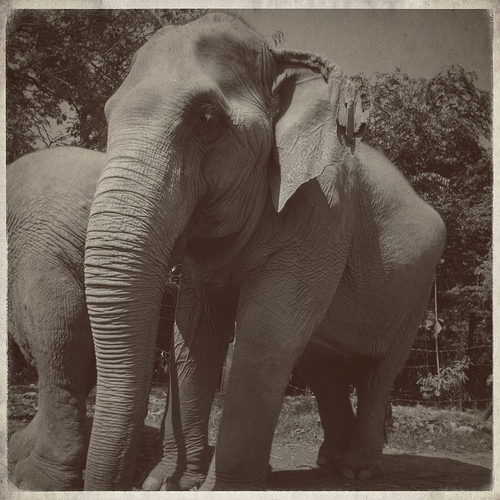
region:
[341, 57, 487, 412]
a tall tree behind the elephant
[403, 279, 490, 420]
a wire fence between the elephant and the trees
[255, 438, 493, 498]
the ground beneath the elephant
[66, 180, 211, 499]
the long elephant trunk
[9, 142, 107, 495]
the second elephant to the left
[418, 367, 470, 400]
some leaves sticking through the fence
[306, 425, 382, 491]
the rear feet of the elephant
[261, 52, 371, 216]
the large ear of the elephant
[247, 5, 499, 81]
the sky above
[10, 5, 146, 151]
the tree in the corner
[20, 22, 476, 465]
two elephants posing for a picture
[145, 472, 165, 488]
a large toe on an elephant foot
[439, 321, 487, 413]
a metal barbed wire fence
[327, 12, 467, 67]
the sky above the elephants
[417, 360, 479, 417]
a plant growing near a fence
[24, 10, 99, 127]
tall trees next the elephant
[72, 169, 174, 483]
a long elephant trunk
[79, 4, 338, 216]
an elephant head with an eye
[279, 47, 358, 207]
a large ear flaps on an elephant head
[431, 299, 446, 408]
a wooden pole supports a fence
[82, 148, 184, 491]
an elephant's trunk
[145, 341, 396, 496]
the elephant's legs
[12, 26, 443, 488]
elephants in a park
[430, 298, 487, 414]
vegetation in the park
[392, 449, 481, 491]
part of the earth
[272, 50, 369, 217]
the elephant's ear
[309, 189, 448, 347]
the elephant's body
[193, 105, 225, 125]
one of the elephant's eye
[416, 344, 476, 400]
part of the park's fence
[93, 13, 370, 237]
a section of the elephant's head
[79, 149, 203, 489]
a trunk of an elephant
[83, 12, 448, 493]
a very huge elephant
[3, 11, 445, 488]
two huge elephants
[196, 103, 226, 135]
an eye of an elephant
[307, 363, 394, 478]
elephant's hind legs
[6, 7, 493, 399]
a bushy area in the background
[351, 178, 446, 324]
a very big belly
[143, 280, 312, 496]
the front legs of an elephant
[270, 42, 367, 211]
an elephant's ear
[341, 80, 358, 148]
some ring on the ear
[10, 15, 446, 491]
Two elephants standing on a field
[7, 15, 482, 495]
Picture is black and white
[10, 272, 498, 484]
Elephants are in a pen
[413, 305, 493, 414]
Pen of elephants are wired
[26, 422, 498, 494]
Shadows of elephants casting in the ground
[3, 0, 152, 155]
Big tree behind elephant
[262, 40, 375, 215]
Ear of elephant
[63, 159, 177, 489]
Trunk of elephant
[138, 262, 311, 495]
Front legs of elephant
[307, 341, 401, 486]
Back legs of elephant